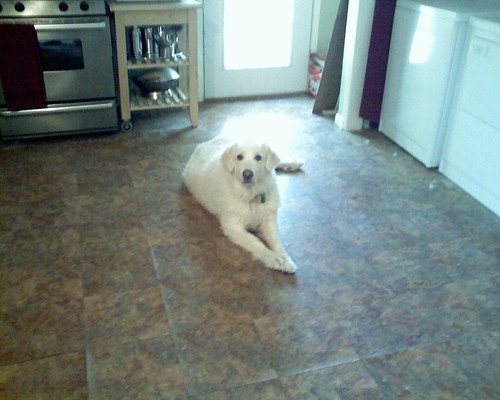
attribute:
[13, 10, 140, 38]
knobs — black 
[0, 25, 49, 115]
maroon towel — maroon 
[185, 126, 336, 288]
dog — large 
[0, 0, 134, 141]
stove — steel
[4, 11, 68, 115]
towel — black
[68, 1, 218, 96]
table — wood 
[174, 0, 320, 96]
door — closed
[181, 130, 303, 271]
dog — yellow, white, reclining , labrador mix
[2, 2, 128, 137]
oven — silver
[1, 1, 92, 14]
knobs — black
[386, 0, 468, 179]
dryer — white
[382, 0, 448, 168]
washer — white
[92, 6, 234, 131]
cart — wood 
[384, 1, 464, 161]
white washer — white 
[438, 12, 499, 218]
white dryer — white 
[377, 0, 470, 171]
washing machine — white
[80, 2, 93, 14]
knob — black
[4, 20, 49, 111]
towel — brown 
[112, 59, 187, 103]
wok — metal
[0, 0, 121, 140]
oven — silver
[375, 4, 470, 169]
appliances — white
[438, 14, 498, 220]
appliances — white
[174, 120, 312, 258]
dog — white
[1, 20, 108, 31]
rack — metal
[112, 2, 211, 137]
kitchen table — butcher block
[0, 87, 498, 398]
tile — linoleum 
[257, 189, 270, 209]
tag — green 